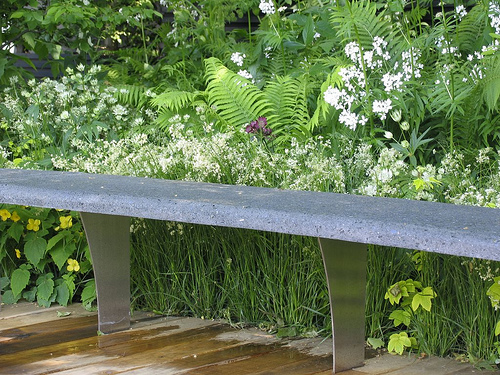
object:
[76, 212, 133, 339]
leg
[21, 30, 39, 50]
leaf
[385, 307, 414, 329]
leaf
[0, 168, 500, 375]
seat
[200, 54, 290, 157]
leaf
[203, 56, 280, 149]
plant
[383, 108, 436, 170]
plant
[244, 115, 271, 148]
plant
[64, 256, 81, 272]
flowers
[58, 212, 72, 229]
flowers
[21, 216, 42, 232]
flowers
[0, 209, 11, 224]
flowers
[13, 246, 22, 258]
flowers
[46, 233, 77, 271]
leaf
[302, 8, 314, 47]
leaf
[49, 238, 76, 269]
leaf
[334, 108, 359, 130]
flowers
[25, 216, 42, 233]
flowers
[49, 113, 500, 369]
bush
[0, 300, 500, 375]
deck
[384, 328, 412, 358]
leaf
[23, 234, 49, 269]
leaf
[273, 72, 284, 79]
leaf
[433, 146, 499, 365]
plant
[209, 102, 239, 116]
leaf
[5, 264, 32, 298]
leaf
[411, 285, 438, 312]
leaf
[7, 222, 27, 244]
leaf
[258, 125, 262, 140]
stem